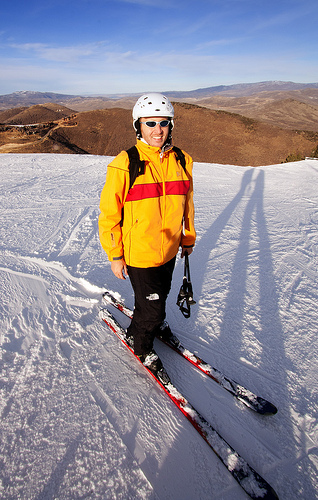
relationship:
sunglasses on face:
[146, 118, 171, 128] [139, 116, 171, 145]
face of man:
[139, 116, 171, 145] [96, 93, 196, 374]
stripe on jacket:
[127, 180, 191, 203] [98, 138, 196, 269]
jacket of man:
[98, 138, 196, 269] [96, 93, 196, 374]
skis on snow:
[96, 292, 280, 500] [0, 152, 316, 499]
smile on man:
[153, 135, 163, 140] [96, 93, 196, 374]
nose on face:
[156, 126, 163, 134] [139, 116, 171, 145]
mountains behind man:
[0, 0, 317, 166] [96, 93, 196, 374]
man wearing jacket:
[96, 93, 196, 374] [98, 138, 196, 269]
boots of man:
[138, 320, 172, 371] [96, 93, 196, 374]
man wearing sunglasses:
[96, 93, 196, 374] [146, 118, 171, 128]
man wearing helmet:
[96, 93, 196, 374] [130, 92, 175, 118]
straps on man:
[127, 146, 187, 189] [96, 93, 196, 374]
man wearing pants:
[96, 93, 196, 374] [127, 256, 175, 354]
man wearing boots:
[96, 93, 196, 374] [138, 320, 172, 371]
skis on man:
[96, 292, 280, 500] [96, 93, 196, 374]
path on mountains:
[0, 111, 80, 155] [0, 0, 317, 166]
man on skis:
[96, 93, 196, 374] [96, 292, 280, 500]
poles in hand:
[177, 251, 197, 318] [179, 246, 192, 259]